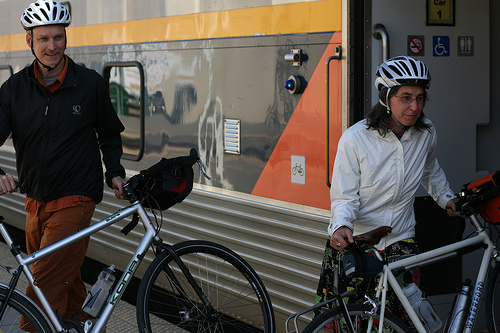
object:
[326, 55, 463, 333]
woman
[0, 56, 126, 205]
jacket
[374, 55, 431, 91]
cap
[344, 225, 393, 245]
seat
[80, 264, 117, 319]
bottle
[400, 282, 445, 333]
bottle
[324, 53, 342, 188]
bar bus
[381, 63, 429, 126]
head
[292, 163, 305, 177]
bike sign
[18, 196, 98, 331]
pants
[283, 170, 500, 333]
bike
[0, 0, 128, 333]
man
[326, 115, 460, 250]
jacket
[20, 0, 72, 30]
cycling helmet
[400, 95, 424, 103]
glasses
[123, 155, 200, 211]
bag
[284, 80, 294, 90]
blue light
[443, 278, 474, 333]
bottle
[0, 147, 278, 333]
bike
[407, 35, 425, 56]
sign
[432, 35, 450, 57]
handicap sign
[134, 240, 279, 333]
wheel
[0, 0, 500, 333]
bus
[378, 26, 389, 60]
bar